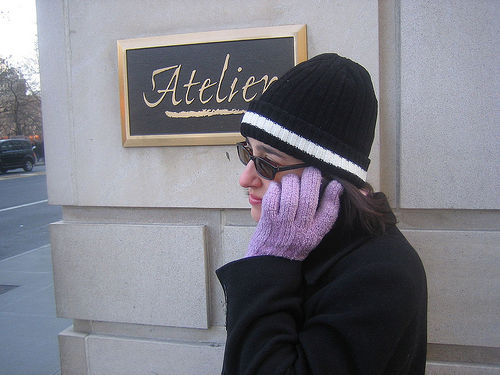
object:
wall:
[60, 79, 222, 168]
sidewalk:
[0, 234, 69, 373]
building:
[37, 0, 499, 374]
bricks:
[37, 0, 379, 207]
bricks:
[49, 219, 209, 329]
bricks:
[57, 331, 227, 374]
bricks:
[399, 1, 499, 210]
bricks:
[400, 229, 499, 347]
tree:
[24, 93, 46, 138]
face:
[238, 137, 304, 222]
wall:
[384, 166, 424, 201]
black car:
[0, 135, 37, 174]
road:
[0, 162, 39, 203]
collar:
[319, 191, 397, 241]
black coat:
[214, 191, 427, 374]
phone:
[310, 175, 331, 213]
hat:
[240, 53, 378, 189]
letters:
[141, 52, 278, 108]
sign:
[115, 23, 309, 147]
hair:
[317, 179, 389, 239]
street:
[3, 205, 44, 242]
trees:
[0, 64, 27, 138]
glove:
[245, 166, 342, 262]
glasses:
[236, 141, 311, 181]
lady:
[215, 52, 427, 375]